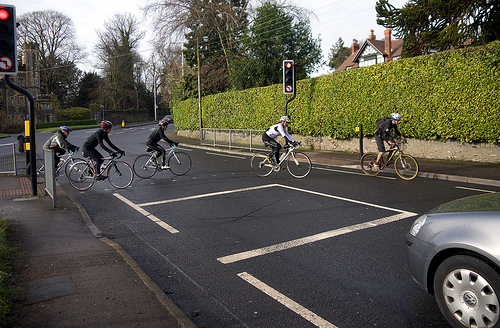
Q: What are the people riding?
A: Bicycles.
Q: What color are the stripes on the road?
A: White.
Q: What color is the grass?
A: Green.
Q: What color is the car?
A: Silver.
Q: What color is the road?
A: Black.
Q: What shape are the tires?
A: Circle.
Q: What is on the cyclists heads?
A: Helmets.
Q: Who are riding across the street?
A: Bicyclists.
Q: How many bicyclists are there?
A: Five.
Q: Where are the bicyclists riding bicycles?
A: Street.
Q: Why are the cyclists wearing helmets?
A: Safety.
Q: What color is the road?
A: Grey.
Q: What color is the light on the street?
A: Red.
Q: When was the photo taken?
A: Bright day.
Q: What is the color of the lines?
A: White.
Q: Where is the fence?
A: Side of street.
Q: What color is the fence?
A: Green.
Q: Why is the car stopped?
A: It's letting the cyclists cross the road.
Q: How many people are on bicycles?
A: Five.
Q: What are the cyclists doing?
A: Crossing the road.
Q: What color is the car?
A: Silver.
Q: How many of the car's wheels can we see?
A: One.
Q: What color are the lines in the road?
A: White.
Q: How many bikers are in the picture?
A: Five.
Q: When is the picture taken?
A: Evening.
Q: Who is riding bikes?
A: People.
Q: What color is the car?
A: Silver.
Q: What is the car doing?
A: Stopping.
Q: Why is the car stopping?
A: To let the bikers cross the street.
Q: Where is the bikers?
A: In front of the car.